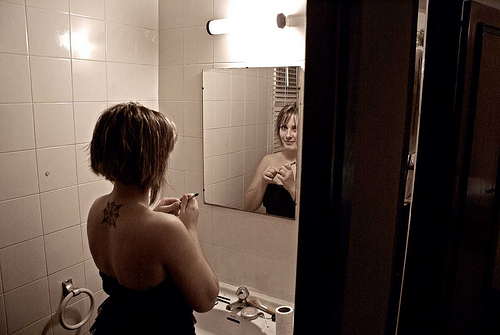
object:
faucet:
[226, 287, 253, 313]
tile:
[33, 102, 78, 149]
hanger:
[56, 286, 97, 329]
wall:
[0, 0, 159, 334]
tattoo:
[102, 200, 121, 227]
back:
[87, 192, 167, 287]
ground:
[308, 157, 349, 195]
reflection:
[56, 22, 103, 62]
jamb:
[343, 1, 421, 331]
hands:
[177, 194, 200, 223]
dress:
[94, 267, 197, 331]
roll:
[274, 305, 294, 333]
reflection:
[244, 70, 301, 219]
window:
[267, 66, 299, 156]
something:
[181, 191, 199, 206]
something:
[278, 157, 295, 170]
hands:
[277, 164, 295, 190]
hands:
[155, 198, 181, 214]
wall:
[160, 0, 297, 302]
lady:
[96, 101, 201, 333]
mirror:
[197, 64, 301, 226]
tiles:
[72, 59, 107, 101]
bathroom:
[3, 1, 309, 329]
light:
[204, 19, 235, 36]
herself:
[243, 100, 299, 218]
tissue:
[272, 306, 297, 335]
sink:
[163, 280, 293, 335]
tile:
[0, 0, 30, 56]